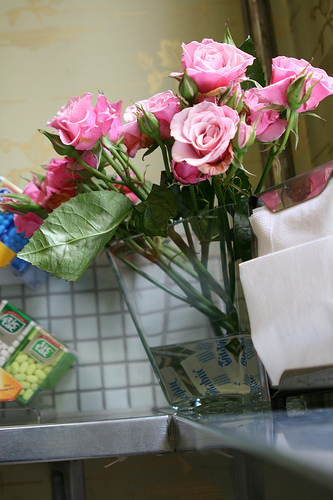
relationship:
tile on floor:
[48, 293, 73, 316] [0, 202, 268, 423]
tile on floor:
[72, 291, 96, 315] [0, 202, 268, 423]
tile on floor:
[94, 289, 122, 316] [0, 202, 268, 423]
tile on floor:
[74, 316, 99, 339] [0, 202, 268, 423]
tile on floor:
[98, 314, 123, 338] [0, 202, 268, 423]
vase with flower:
[97, 208, 289, 446] [157, 99, 244, 178]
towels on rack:
[220, 195, 327, 374] [265, 359, 321, 397]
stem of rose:
[180, 197, 268, 355] [167, 105, 240, 178]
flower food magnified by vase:
[161, 351, 252, 395] [109, 204, 259, 407]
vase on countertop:
[97, 208, 289, 446] [56, 252, 263, 406]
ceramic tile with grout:
[14, 281, 173, 414] [93, 290, 109, 403]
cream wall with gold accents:
[1, 1, 252, 190] [135, 36, 183, 92]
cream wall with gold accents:
[1, 1, 252, 190] [0, 2, 150, 49]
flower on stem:
[157, 99, 244, 178] [207, 172, 236, 302]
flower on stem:
[46, 89, 116, 151] [92, 155, 175, 222]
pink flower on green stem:
[6, 184, 44, 228] [18, 191, 57, 226]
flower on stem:
[46, 89, 116, 151] [84, 130, 242, 339]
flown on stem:
[5, 10, 322, 291] [96, 123, 278, 317]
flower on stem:
[176, 35, 248, 85] [257, 151, 276, 183]